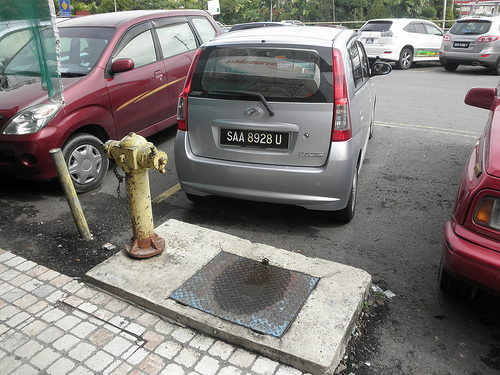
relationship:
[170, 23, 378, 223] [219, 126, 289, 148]
minivan has license plate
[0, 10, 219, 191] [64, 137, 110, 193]
van has front tire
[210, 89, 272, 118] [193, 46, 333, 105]
wiper on windshield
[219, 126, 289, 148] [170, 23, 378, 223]
license plate attached to minivan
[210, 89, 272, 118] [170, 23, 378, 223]
wiper attached to minivan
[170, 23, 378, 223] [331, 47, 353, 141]
minivan has tail lights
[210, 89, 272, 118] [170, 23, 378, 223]
wiper on minivan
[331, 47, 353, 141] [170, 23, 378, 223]
tail lights are on minivan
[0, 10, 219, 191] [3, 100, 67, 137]
van has headlight